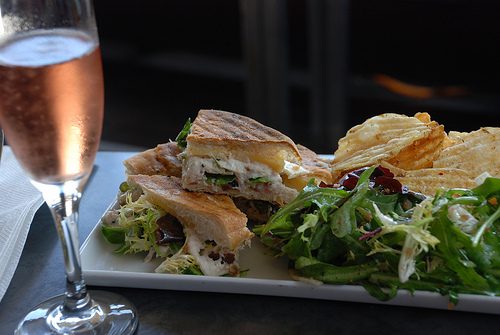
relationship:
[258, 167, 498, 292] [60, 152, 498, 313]
salad lying on plate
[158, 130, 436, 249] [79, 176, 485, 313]
food lying on dish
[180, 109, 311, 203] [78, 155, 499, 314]
food on plate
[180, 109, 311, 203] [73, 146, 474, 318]
food on plate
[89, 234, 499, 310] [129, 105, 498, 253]
plate with food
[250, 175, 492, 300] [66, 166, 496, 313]
lettuce on plate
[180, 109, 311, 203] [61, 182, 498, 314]
food on dish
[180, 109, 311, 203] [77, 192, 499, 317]
food on a dish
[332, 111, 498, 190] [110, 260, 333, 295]
chips on plate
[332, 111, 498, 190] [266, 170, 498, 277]
chips next to lettuce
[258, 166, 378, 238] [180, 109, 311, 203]
lettuce on food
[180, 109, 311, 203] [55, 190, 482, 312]
food on dish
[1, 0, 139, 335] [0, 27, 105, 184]
wine glass filled with wine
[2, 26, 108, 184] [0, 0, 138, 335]
wine in wine glass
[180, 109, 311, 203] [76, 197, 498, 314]
food in plate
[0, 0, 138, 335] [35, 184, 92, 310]
wine glass has stem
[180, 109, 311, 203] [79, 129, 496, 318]
food on plate